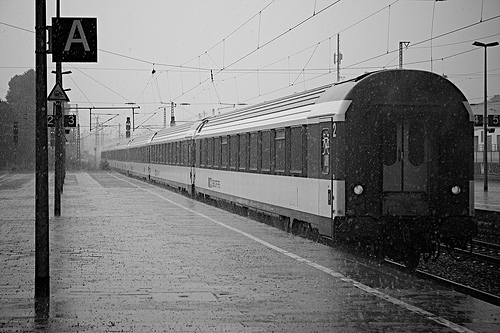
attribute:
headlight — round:
[340, 171, 471, 213]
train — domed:
[142, 90, 436, 244]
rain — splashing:
[359, 234, 411, 271]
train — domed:
[95, 109, 222, 223]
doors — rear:
[371, 105, 437, 229]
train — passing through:
[139, 103, 217, 194]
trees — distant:
[8, 45, 59, 176]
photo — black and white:
[80, 98, 448, 308]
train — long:
[85, 112, 212, 238]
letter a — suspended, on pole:
[41, 14, 99, 75]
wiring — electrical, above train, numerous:
[106, 4, 498, 120]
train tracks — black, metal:
[420, 200, 499, 301]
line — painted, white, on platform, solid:
[95, 164, 459, 333]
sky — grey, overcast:
[0, 3, 499, 123]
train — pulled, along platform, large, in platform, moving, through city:
[94, 69, 479, 271]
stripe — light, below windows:
[97, 160, 348, 200]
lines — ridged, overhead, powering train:
[102, 77, 337, 152]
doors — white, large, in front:
[376, 110, 432, 201]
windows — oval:
[384, 121, 427, 164]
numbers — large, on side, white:
[43, 112, 78, 158]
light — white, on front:
[345, 179, 465, 209]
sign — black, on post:
[49, 14, 99, 67]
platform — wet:
[1, 152, 499, 333]